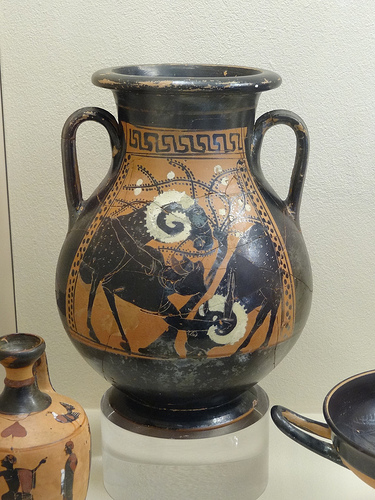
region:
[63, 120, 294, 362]
A picture of rams.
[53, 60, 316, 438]
An old ethnic vase.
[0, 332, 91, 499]
A very old vase.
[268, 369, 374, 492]
An old piece of pottery.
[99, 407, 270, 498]
A white pottery stand.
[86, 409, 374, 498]
A white countertop.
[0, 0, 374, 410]
A white background wall.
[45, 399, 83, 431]
A rendering of a chicken.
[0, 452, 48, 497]
A drawing of a human.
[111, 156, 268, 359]
A picture of a tree.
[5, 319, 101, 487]
THAT IS A VASE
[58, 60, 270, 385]
THAT IS A VASE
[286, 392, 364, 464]
THAT IS A VASE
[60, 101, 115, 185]
THE HANDLE OF THE VASE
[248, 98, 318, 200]
THE HANDLE OF THE VASE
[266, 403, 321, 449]
THE HANDLE OF THE VASE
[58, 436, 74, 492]
A DRAWING ON THE VASE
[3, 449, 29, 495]
A DRAWING ON THE VASE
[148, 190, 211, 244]
A DRAWING ON THE VASE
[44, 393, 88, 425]
A DRAWING ON THE VASE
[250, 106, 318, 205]
handle on a vase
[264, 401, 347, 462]
handle on a vase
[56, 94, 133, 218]
handle on a vase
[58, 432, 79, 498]
painting of a person on a vase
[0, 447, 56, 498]
painting of a person on a vase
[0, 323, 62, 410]
spout of a vase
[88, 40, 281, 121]
spout of a vase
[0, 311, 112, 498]
old looking vase with paintings on it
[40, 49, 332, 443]
old looking vase with paintings on it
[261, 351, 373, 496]
old looking vase with handle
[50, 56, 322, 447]
Black and brown vase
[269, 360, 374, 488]
Black and brown pot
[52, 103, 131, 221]
One black and brown handle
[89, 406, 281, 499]
Clear stand for pretty vase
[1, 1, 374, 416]
Plain white wall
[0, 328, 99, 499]
Small brown and black vase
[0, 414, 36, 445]
Red spades design on vase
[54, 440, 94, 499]
black man on vase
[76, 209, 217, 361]
Black bull on vase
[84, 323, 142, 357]
Black bull hooves on vase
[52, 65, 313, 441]
A black and brown vase.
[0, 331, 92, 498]
A tan and black vase.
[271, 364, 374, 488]
A piece of black pottery.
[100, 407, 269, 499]
A white vase stand.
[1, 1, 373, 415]
A textured white wall.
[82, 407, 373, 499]
A white display shelf.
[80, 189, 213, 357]
Drawing of a ram.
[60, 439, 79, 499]
Drawing of a person.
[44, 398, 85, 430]
Drawing of a bird.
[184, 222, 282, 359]
Black ram with white horns.